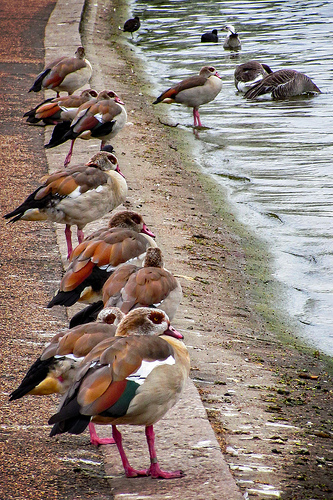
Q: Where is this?
A: This is at the lake.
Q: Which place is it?
A: It is a lake.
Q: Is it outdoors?
A: Yes, it is outdoors.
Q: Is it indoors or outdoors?
A: It is outdoors.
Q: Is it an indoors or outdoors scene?
A: It is outdoors.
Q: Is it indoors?
A: No, it is outdoors.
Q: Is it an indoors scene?
A: No, it is outdoors.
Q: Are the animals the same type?
A: No, they are birds and ducks.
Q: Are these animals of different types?
A: Yes, they are birds and ducks.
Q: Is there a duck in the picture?
A: Yes, there is a duck.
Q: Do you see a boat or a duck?
A: Yes, there is a duck.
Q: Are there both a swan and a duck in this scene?
A: No, there is a duck but no swans.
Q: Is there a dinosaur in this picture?
A: No, there are no dinosaurs.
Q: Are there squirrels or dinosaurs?
A: No, there are no dinosaurs or squirrels.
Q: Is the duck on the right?
A: Yes, the duck is on the right of the image.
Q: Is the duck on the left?
A: No, the duck is on the right of the image.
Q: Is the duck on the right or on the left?
A: The duck is on the right of the image.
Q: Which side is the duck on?
A: The duck is on the right of the image.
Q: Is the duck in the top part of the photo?
A: Yes, the duck is in the top of the image.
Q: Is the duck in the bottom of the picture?
A: No, the duck is in the top of the image.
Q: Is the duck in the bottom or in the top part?
A: The duck is in the top of the image.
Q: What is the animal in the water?
A: The animal is a duck.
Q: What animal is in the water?
A: The animal is a duck.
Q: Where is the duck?
A: The duck is in the water.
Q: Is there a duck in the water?
A: Yes, there is a duck in the water.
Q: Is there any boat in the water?
A: No, there is a duck in the water.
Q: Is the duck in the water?
A: Yes, the duck is in the water.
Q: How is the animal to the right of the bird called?
A: The animal is a duck.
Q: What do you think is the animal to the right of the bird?
A: The animal is a duck.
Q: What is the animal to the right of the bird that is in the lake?
A: The animal is a duck.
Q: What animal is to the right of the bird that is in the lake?
A: The animal is a duck.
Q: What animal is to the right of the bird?
A: The animal is a duck.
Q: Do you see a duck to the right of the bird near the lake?
A: Yes, there is a duck to the right of the bird.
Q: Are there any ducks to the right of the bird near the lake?
A: Yes, there is a duck to the right of the bird.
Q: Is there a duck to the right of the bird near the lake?
A: Yes, there is a duck to the right of the bird.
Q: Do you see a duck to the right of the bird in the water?
A: Yes, there is a duck to the right of the bird.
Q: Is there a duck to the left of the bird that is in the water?
A: No, the duck is to the right of the bird.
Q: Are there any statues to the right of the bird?
A: No, there is a duck to the right of the bird.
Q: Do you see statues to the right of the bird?
A: No, there is a duck to the right of the bird.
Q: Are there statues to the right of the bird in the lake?
A: No, there is a duck to the right of the bird.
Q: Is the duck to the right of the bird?
A: Yes, the duck is to the right of the bird.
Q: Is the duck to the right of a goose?
A: No, the duck is to the right of the bird.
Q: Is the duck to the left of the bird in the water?
A: No, the duck is to the right of the bird.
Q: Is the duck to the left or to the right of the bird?
A: The duck is to the right of the bird.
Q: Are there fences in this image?
A: No, there are no fences.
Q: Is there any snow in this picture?
A: Yes, there is snow.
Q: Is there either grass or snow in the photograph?
A: Yes, there is snow.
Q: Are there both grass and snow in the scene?
A: No, there is snow but no grass.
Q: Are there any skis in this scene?
A: No, there are no skis.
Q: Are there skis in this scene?
A: No, there are no skis.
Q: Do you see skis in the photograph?
A: No, there are no skis.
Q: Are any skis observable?
A: No, there are no skis.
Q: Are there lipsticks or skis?
A: No, there are no skis or lipsticks.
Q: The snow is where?
A: The snow is on the ground.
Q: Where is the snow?
A: The snow is on the ground.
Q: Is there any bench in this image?
A: No, there are no benches.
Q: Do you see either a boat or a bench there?
A: No, there are no benches or boats.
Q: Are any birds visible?
A: Yes, there is a bird.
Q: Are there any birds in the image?
A: Yes, there is a bird.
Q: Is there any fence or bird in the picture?
A: Yes, there is a bird.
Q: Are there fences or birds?
A: Yes, there is a bird.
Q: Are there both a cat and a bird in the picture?
A: No, there is a bird but no cats.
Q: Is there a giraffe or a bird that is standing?
A: Yes, the bird is standing.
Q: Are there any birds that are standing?
A: Yes, there is a bird that is standing.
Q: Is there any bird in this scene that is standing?
A: Yes, there is a bird that is standing.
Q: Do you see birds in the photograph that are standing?
A: Yes, there is a bird that is standing.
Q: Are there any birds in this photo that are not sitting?
A: Yes, there is a bird that is standing.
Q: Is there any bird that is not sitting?
A: Yes, there is a bird that is standing.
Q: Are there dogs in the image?
A: No, there are no dogs.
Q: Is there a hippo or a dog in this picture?
A: No, there are no dogs or hippos.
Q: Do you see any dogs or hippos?
A: No, there are no dogs or hippos.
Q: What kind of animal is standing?
A: The animal is a bird.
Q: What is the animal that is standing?
A: The animal is a bird.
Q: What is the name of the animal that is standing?
A: The animal is a bird.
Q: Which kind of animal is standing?
A: The animal is a bird.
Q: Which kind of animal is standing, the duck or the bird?
A: The bird is standing.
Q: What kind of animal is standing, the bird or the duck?
A: The bird is standing.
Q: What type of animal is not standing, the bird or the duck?
A: The duck is not standing.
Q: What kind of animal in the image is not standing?
A: The animal is a duck.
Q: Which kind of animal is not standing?
A: The animal is a duck.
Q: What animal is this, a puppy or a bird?
A: This is a bird.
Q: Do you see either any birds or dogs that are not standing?
A: No, there is a bird but it is standing.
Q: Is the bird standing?
A: Yes, the bird is standing.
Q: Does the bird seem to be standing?
A: Yes, the bird is standing.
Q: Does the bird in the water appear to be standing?
A: Yes, the bird is standing.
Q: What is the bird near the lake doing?
A: The bird is standing.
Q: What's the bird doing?
A: The bird is standing.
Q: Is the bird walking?
A: No, the bird is standing.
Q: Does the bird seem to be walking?
A: No, the bird is standing.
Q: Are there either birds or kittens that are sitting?
A: No, there is a bird but it is standing.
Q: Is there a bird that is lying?
A: No, there is a bird but it is standing.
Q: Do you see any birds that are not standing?
A: No, there is a bird but it is standing.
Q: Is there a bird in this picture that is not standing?
A: No, there is a bird but it is standing.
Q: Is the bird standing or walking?
A: The bird is standing.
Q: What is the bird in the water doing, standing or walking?
A: The bird is standing.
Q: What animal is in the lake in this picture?
A: The bird is in the lake.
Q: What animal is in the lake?
A: The bird is in the lake.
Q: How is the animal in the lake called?
A: The animal is a bird.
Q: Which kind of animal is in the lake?
A: The animal is a bird.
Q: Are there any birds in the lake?
A: Yes, there is a bird in the lake.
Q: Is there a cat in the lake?
A: No, there is a bird in the lake.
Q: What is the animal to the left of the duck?
A: The animal is a bird.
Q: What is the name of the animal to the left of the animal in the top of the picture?
A: The animal is a bird.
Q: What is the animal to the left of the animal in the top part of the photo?
A: The animal is a bird.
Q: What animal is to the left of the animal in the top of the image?
A: The animal is a bird.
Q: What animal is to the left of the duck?
A: The animal is a bird.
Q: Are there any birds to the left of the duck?
A: Yes, there is a bird to the left of the duck.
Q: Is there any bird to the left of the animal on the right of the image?
A: Yes, there is a bird to the left of the duck.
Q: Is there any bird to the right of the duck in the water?
A: No, the bird is to the left of the duck.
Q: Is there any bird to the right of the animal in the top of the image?
A: No, the bird is to the left of the duck.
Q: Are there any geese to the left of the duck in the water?
A: No, there is a bird to the left of the duck.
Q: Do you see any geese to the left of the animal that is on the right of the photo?
A: No, there is a bird to the left of the duck.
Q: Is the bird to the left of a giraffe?
A: No, the bird is to the left of the duck.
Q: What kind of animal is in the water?
A: The animal is a bird.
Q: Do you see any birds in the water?
A: Yes, there is a bird in the water.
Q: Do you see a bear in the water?
A: No, there is a bird in the water.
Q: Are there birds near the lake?
A: Yes, there is a bird near the lake.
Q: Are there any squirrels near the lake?
A: No, there is a bird near the lake.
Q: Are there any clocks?
A: No, there are no clocks.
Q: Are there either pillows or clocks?
A: No, there are no clocks or pillows.